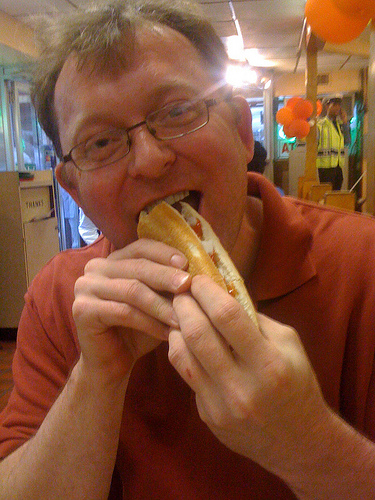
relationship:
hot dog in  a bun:
[172, 208, 242, 310] [138, 199, 258, 330]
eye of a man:
[159, 98, 194, 121] [0, 0, 375, 498]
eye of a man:
[65, 115, 140, 163] [9, 37, 369, 312]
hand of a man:
[162, 292, 318, 442] [13, 27, 283, 329]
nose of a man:
[127, 125, 175, 179] [0, 0, 375, 498]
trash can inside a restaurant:
[0, 169, 59, 342] [0, 1, 372, 414]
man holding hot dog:
[36, 16, 308, 288] [145, 200, 265, 333]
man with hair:
[0, 0, 375, 498] [23, 0, 243, 212]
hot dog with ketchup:
[134, 189, 263, 354] [187, 216, 202, 237]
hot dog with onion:
[134, 189, 263, 354] [202, 238, 213, 255]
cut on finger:
[182, 364, 194, 381] [163, 326, 210, 392]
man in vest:
[0, 0, 375, 498] [313, 117, 347, 170]